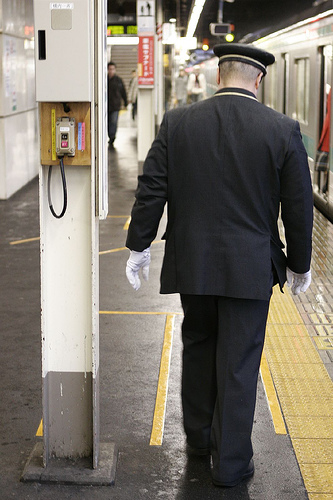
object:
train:
[184, 5, 333, 226]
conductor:
[124, 40, 315, 491]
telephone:
[46, 115, 76, 219]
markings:
[98, 305, 174, 450]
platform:
[0, 109, 333, 500]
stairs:
[109, 43, 138, 103]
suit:
[123, 85, 315, 489]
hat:
[211, 40, 276, 78]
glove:
[125, 243, 152, 292]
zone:
[9, 212, 333, 500]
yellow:
[264, 281, 333, 500]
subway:
[0, 0, 333, 500]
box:
[38, 100, 93, 168]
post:
[19, 0, 120, 490]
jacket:
[123, 84, 315, 302]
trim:
[210, 90, 259, 103]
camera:
[208, 0, 233, 38]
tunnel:
[0, 0, 333, 500]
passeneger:
[313, 84, 332, 195]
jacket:
[316, 92, 330, 154]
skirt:
[313, 149, 331, 174]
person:
[106, 60, 129, 145]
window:
[291, 56, 309, 127]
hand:
[125, 246, 151, 291]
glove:
[285, 266, 314, 297]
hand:
[284, 267, 312, 296]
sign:
[137, 35, 155, 91]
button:
[61, 141, 68, 148]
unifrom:
[124, 41, 317, 486]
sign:
[106, 23, 139, 36]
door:
[105, 33, 140, 47]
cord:
[47, 154, 68, 219]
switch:
[59, 126, 70, 150]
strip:
[263, 336, 292, 497]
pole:
[134, 0, 157, 180]